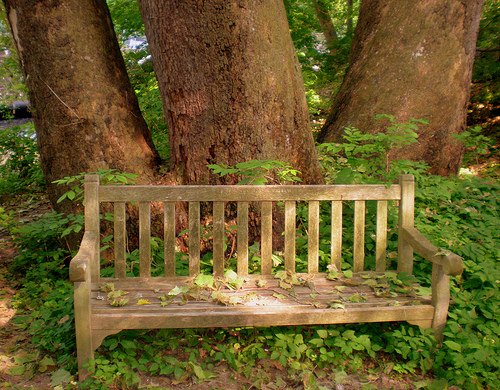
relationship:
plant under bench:
[210, 335, 313, 372] [71, 164, 452, 354]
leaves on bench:
[194, 269, 237, 306] [71, 164, 452, 354]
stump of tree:
[27, 159, 183, 253] [3, 7, 168, 220]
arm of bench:
[401, 222, 466, 281] [71, 164, 452, 354]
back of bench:
[104, 176, 390, 263] [71, 164, 452, 354]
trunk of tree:
[145, 11, 324, 165] [3, 7, 168, 220]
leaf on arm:
[428, 243, 449, 261] [401, 222, 466, 281]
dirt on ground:
[215, 367, 247, 389] [27, 332, 329, 389]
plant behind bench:
[337, 122, 411, 168] [71, 164, 452, 354]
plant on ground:
[210, 335, 313, 372] [27, 332, 329, 389]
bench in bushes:
[71, 164, 452, 354] [345, 128, 484, 360]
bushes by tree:
[345, 128, 484, 360] [3, 7, 168, 220]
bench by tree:
[71, 164, 452, 354] [3, 7, 168, 220]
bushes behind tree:
[117, 24, 178, 154] [3, 7, 168, 220]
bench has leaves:
[71, 164, 452, 354] [194, 269, 237, 306]